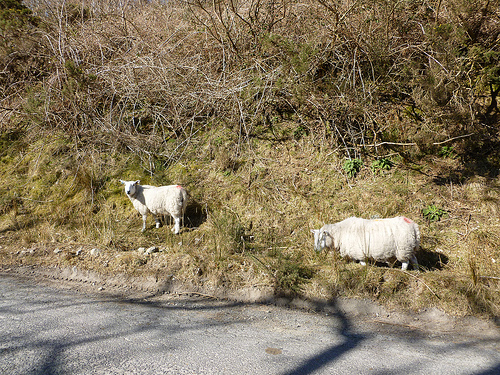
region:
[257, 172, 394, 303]
the sheep is sniffing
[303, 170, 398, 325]
the sheep is sniffing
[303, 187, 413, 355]
the sheep is sniffing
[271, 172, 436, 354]
the sheep is sniffing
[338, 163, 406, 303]
the sheep is sniffing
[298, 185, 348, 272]
the sheep is sniffing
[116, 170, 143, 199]
the head of a sheep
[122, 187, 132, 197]
the nose of a sheep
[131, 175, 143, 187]
the ear of a sheep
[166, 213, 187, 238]
the hind legs of a sheep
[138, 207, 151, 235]
the front leg of a sheep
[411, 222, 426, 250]
the tail of a sheep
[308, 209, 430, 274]
a fluffy white sheep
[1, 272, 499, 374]
a gray paved road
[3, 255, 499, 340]
brown dirt by the road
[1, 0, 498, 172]
twigs on the hill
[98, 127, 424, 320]
the sheep is white and furry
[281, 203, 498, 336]
the sheep is white and furry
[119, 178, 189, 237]
A sheep looking at the camera.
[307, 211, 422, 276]
A larger white sheep grazing.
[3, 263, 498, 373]
A paved road.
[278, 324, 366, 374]
A thick branch shadow on the road.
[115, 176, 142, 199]
Head of a sheep looking at the camera.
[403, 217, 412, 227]
Colored dot on the rear of a larger sheep.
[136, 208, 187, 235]
Four legs of a smaller sheep.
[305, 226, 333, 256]
Head of a larger sheep.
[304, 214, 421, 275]
Larger sheep on a hill.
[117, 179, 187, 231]
Smaller sheep to the left of a larger sheep.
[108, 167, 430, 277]
Two sheep.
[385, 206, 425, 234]
The sheep have red spots on their back.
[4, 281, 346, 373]
The road is gray.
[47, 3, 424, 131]
A lot of dead plants.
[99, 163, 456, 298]
The sheep are on the side of the road.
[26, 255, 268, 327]
Tracks are in the mud.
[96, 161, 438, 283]
The sheep are white.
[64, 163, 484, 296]
The sheep are grazing.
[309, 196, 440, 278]
The sheep on the right is larger.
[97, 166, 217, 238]
The sheep on the left is looking at the camera.